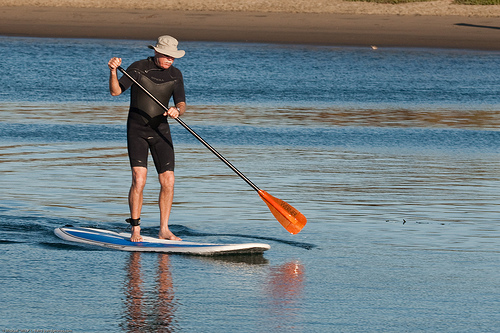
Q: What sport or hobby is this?
A: Paddle Boarding.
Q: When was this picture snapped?
A: Daytime.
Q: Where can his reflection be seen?
A: On the water.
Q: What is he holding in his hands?
A: An oar.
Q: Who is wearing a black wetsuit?
A: The man.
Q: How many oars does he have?
A: 1.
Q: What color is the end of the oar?
A: Orange.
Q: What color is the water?
A: Deep blue.